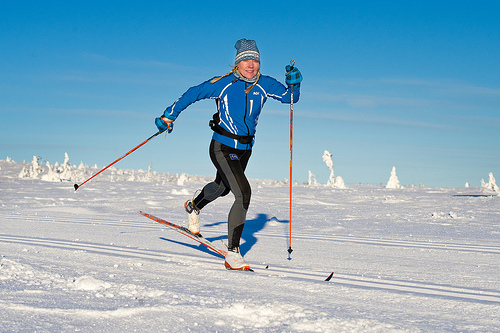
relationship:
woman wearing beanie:
[150, 35, 314, 280] [226, 37, 269, 66]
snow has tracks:
[4, 159, 496, 332] [5, 230, 240, 284]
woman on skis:
[150, 35, 314, 280] [130, 208, 344, 304]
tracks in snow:
[5, 230, 240, 284] [4, 159, 496, 332]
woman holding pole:
[150, 35, 314, 280] [284, 86, 306, 261]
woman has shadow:
[150, 35, 314, 280] [165, 212, 300, 274]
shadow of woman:
[165, 212, 300, 274] [150, 35, 314, 280]